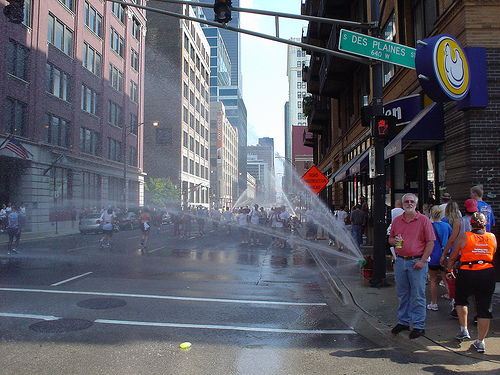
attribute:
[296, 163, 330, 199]
sign — orange, construction, black, bright orange, don't walk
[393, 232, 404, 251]
bottle — mans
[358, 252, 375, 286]
hydrant — red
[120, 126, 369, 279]
water — spraying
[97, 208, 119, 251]
people — running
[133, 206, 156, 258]
people — running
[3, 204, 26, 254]
people — running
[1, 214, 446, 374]
street — paved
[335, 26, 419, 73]
sign — green, white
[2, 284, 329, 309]
lines — white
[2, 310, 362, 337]
lines — white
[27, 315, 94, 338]
covers — man hole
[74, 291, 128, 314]
covers — man hole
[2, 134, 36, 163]
flag — hanging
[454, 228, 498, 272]
shirt — bright orange, orange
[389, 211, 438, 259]
shirt — pink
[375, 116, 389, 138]
signal — red, for pedestrians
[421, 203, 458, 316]
woman — blonde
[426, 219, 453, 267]
shirt — blue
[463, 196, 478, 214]
cap — red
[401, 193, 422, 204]
hair — gray